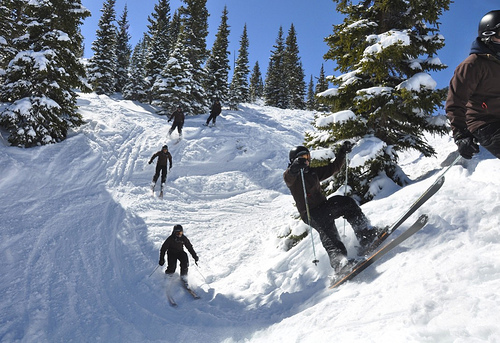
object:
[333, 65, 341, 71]
leaf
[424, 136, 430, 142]
leaf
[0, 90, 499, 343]
hill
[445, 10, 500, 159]
skier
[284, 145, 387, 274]
skier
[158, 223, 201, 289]
skier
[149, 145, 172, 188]
skier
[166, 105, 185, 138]
skier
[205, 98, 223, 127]
skier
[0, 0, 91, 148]
plant